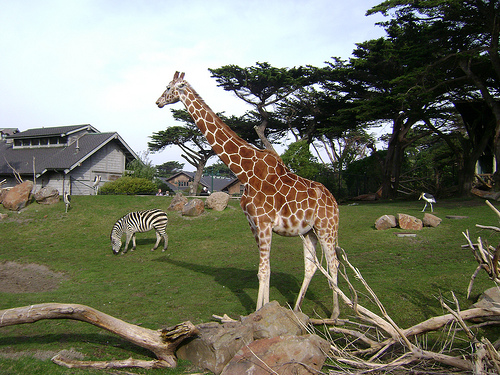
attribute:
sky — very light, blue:
[20, 28, 107, 99]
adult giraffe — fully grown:
[156, 69, 343, 324]